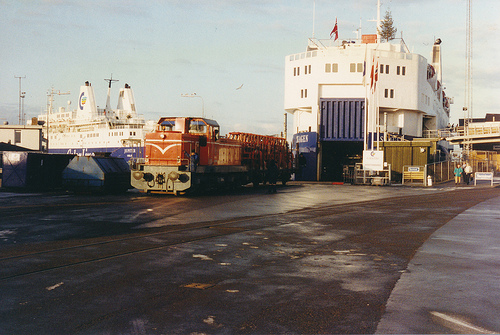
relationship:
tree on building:
[377, 7, 401, 35] [284, 36, 442, 186]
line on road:
[152, 268, 223, 308] [1, 198, 479, 265]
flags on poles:
[352, 58, 385, 86] [361, 68, 387, 161]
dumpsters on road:
[4, 148, 127, 203] [1, 198, 479, 265]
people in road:
[444, 151, 474, 187] [1, 187, 500, 334]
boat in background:
[27, 73, 147, 168] [16, 22, 477, 193]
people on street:
[444, 151, 474, 187] [8, 173, 482, 331]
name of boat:
[118, 142, 142, 158] [27, 73, 147, 168]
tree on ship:
[377, 7, 401, 35] [275, 42, 468, 178]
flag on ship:
[328, 16, 343, 46] [275, 42, 468, 178]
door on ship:
[316, 94, 371, 174] [275, 42, 468, 178]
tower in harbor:
[463, 10, 475, 187] [1, 13, 497, 264]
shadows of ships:
[1, 187, 349, 249] [1, 32, 468, 209]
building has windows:
[284, 36, 442, 186] [288, 58, 406, 78]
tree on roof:
[377, 7, 401, 35] [293, 47, 441, 71]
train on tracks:
[126, 115, 239, 191] [119, 191, 163, 202]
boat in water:
[27, 85, 148, 172] [26, 155, 120, 196]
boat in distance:
[27, 85, 148, 172] [5, 65, 483, 161]